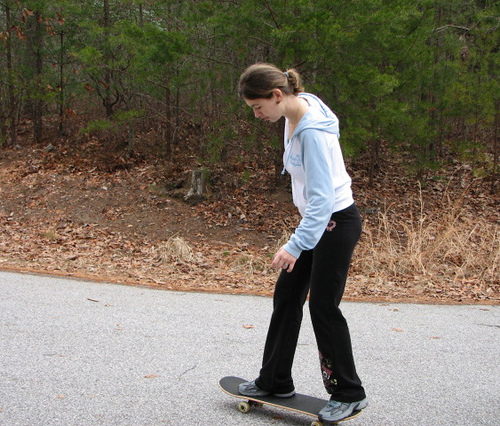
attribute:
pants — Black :
[253, 199, 372, 403]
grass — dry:
[0, 196, 496, 283]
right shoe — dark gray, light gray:
[235, 374, 294, 396]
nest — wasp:
[456, 37, 475, 72]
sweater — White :
[273, 90, 358, 262]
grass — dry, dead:
[350, 178, 499, 284]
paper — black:
[218, 377, 331, 414]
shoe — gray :
[235, 379, 299, 400]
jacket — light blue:
[278, 92, 355, 257]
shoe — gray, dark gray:
[239, 368, 294, 399]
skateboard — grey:
[219, 376, 361, 424]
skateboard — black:
[211, 365, 363, 409]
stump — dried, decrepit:
[172, 163, 209, 205]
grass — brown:
[371, 201, 497, 301]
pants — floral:
[228, 216, 402, 371]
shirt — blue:
[263, 87, 354, 257]